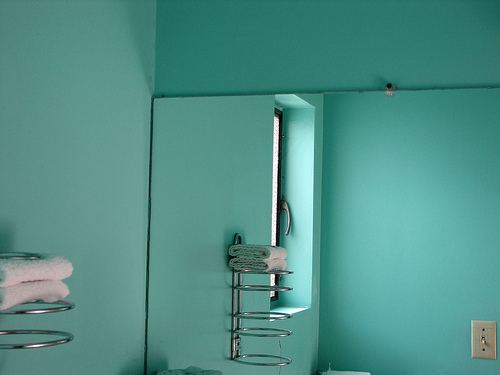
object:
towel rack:
[0, 251, 76, 350]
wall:
[0, 0, 155, 375]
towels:
[0, 253, 73, 310]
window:
[269, 94, 314, 323]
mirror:
[270, 108, 287, 296]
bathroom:
[0, 0, 499, 374]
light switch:
[471, 320, 497, 360]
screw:
[386, 83, 393, 90]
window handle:
[281, 201, 291, 235]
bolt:
[482, 328, 485, 331]